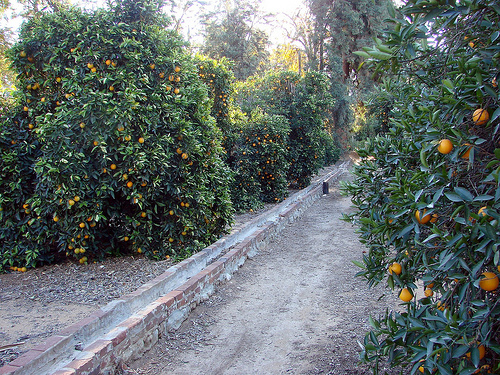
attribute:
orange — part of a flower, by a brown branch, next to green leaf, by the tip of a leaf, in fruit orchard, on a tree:
[434, 137, 456, 157]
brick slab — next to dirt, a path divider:
[2, 155, 370, 372]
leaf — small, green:
[369, 49, 396, 61]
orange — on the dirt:
[164, 252, 172, 259]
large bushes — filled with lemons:
[0, 2, 238, 272]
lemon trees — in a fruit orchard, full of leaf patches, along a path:
[5, 6, 356, 274]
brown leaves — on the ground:
[0, 153, 394, 374]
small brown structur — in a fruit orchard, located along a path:
[321, 178, 332, 197]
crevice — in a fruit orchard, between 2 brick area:
[9, 151, 362, 374]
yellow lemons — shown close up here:
[438, 136, 478, 164]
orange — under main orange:
[415, 208, 433, 228]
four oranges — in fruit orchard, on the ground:
[9, 264, 28, 273]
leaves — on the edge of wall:
[173, 225, 239, 266]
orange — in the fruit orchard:
[384, 260, 403, 277]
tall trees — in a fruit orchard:
[311, 2, 410, 157]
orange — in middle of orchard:
[269, 139, 274, 146]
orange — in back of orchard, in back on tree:
[326, 118, 331, 125]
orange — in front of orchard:
[66, 199, 75, 209]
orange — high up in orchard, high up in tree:
[19, 48, 28, 61]